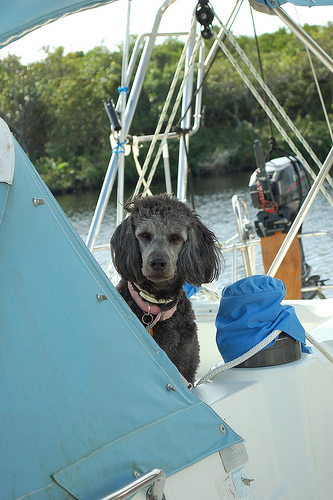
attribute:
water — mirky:
[197, 178, 233, 226]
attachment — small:
[31, 197, 45, 206]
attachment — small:
[95, 290, 109, 303]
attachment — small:
[165, 378, 181, 392]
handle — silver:
[93, 461, 156, 493]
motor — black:
[225, 152, 330, 236]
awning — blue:
[0, 0, 120, 53]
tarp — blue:
[214, 274, 313, 362]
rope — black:
[245, 0, 311, 205]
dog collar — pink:
[121, 277, 207, 318]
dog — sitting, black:
[112, 191, 215, 384]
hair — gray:
[135, 214, 183, 281]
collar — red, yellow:
[125, 279, 178, 337]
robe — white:
[195, 327, 317, 387]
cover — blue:
[0, 1, 331, 498]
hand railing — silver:
[96, 465, 167, 499]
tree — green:
[3, 43, 170, 195]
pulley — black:
[196, 0, 214, 39]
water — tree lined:
[54, 168, 332, 302]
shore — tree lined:
[54, 168, 332, 216]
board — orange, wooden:
[259, 233, 300, 298]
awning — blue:
[0, 0, 117, 48]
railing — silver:
[104, 457, 164, 498]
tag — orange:
[146, 321, 153, 339]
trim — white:
[0, 3, 104, 45]